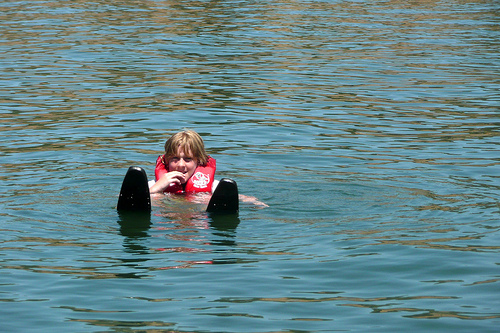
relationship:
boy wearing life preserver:
[140, 137, 233, 206] [154, 153, 217, 200]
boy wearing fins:
[140, 137, 233, 206] [116, 166, 152, 215]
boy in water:
[140, 137, 233, 206] [50, 56, 460, 305]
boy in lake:
[140, 137, 233, 206] [33, 34, 470, 201]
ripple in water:
[236, 106, 437, 160] [50, 56, 460, 305]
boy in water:
[148, 129, 270, 208] [50, 56, 460, 305]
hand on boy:
[159, 173, 191, 192] [148, 129, 270, 208]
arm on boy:
[145, 172, 177, 194] [148, 129, 270, 208]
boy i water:
[148, 129, 270, 208] [50, 56, 460, 305]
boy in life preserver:
[148, 129, 270, 208] [154, 153, 217, 200]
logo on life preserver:
[193, 172, 204, 192] [150, 158, 247, 195]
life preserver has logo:
[150, 158, 247, 195] [193, 172, 204, 192]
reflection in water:
[114, 236, 326, 281] [50, 56, 460, 305]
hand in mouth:
[159, 173, 191, 192] [176, 167, 195, 176]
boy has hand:
[148, 129, 270, 208] [159, 173, 191, 192]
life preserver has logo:
[154, 153, 217, 200] [193, 172, 204, 192]